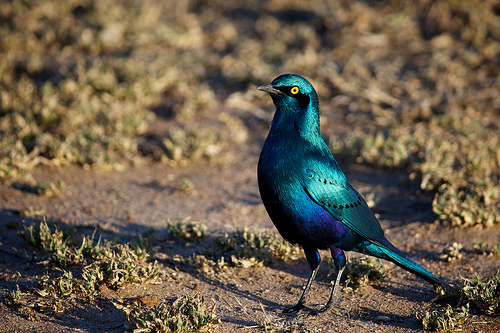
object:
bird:
[253, 72, 441, 318]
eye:
[291, 86, 301, 94]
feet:
[305, 264, 343, 319]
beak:
[256, 83, 279, 94]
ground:
[0, 1, 499, 333]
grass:
[1, 1, 499, 333]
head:
[254, 72, 318, 106]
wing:
[297, 151, 412, 266]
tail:
[359, 241, 447, 291]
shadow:
[0, 207, 295, 316]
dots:
[321, 176, 328, 185]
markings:
[299, 93, 311, 111]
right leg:
[284, 246, 322, 317]